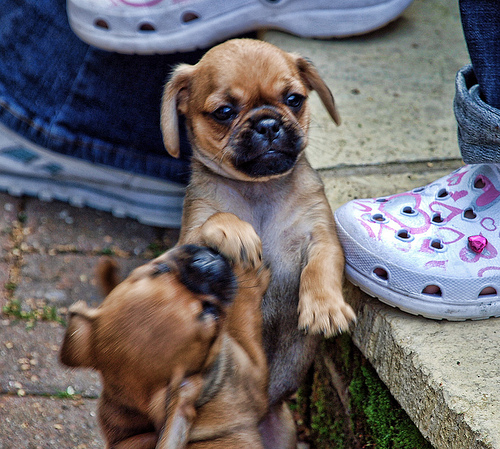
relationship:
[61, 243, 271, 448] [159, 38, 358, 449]
puppy jumping on puppy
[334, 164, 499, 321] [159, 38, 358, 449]
croc to right of puppy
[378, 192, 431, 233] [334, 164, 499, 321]
heart printed on croc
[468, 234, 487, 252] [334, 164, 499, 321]
heart on top of croc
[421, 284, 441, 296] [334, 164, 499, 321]
hole cut into croc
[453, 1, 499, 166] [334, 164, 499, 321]
pant-leg above croc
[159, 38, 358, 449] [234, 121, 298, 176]
puppy has muzzle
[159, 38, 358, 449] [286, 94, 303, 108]
puppy has eye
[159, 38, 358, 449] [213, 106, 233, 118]
puppy has eye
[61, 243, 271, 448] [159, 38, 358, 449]
puppy playing with puppy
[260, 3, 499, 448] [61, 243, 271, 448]
step next to puppy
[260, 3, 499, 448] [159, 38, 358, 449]
step next to puppy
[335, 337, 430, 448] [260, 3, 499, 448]
moss growing on step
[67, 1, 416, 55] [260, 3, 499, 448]
shoe on step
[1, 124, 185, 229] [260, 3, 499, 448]
shoe beside step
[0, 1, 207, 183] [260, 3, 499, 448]
pant-leg next to step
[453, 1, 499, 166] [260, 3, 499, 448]
pant-leg on step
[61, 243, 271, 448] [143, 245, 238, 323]
puppy has face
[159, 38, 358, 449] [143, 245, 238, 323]
puppy pawing face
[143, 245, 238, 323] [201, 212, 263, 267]
face getting pawed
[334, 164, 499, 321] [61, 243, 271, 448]
croc next to puppy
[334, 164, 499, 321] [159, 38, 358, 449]
croc next to puppy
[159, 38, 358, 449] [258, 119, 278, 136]
puppy has nose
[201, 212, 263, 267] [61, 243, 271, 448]
pawed on puppy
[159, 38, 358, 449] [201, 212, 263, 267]
puppy has pawed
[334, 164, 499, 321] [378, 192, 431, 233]
croc has heart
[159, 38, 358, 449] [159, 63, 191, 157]
puppy has ear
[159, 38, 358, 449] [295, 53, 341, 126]
puppy has ear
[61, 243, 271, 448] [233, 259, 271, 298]
puppy has claw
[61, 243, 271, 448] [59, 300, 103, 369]
puppy has ear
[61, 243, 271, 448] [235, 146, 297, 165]
puppy has mouth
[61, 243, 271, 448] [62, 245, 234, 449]
puppy has head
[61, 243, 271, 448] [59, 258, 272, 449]
puppy has fur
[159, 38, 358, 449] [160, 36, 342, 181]
puppy has head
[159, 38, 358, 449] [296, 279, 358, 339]
puppy has paw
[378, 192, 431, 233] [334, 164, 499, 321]
heart on croc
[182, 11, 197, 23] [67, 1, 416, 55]
hole in shoe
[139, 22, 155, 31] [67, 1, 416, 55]
hole in shoe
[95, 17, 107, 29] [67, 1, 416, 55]
hole in shoe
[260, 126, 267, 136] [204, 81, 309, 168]
nostril on face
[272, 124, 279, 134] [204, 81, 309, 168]
nostril on face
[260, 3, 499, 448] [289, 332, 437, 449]
step has side